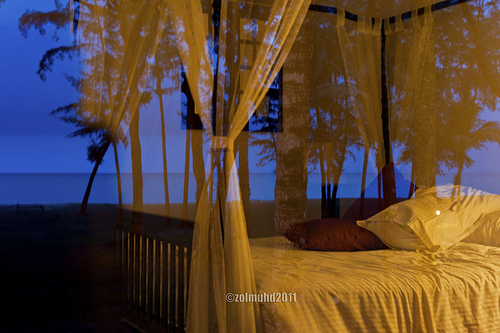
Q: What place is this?
A: It is a beach.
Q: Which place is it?
A: It is a beach.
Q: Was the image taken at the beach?
A: Yes, it was taken in the beach.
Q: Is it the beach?
A: Yes, it is the beach.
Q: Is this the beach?
A: Yes, it is the beach.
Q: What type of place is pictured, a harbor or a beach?
A: It is a beach.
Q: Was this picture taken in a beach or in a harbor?
A: It was taken at a beach.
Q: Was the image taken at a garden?
A: No, the picture was taken in a beach.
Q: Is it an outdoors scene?
A: Yes, it is outdoors.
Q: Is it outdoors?
A: Yes, it is outdoors.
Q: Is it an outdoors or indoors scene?
A: It is outdoors.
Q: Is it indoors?
A: No, it is outdoors.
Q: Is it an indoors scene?
A: No, it is outdoors.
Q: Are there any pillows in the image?
A: Yes, there are pillows.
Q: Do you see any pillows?
A: Yes, there are pillows.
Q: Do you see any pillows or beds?
A: Yes, there are pillows.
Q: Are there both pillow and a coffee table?
A: No, there are pillows but no coffee tables.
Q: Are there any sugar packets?
A: No, there are no sugar packets.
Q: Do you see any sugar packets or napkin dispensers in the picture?
A: No, there are no sugar packets or napkin dispensers.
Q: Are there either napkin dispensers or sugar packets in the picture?
A: No, there are no sugar packets or napkin dispensers.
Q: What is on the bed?
A: The pillows are on the bed.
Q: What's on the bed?
A: The pillows are on the bed.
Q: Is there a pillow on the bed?
A: Yes, there are pillows on the bed.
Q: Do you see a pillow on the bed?
A: Yes, there are pillows on the bed.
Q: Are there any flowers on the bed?
A: No, there are pillows on the bed.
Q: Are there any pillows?
A: Yes, there is a pillow.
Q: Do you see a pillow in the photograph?
A: Yes, there is a pillow.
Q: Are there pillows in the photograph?
A: Yes, there is a pillow.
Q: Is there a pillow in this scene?
A: Yes, there is a pillow.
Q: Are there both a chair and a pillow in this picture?
A: No, there is a pillow but no chairs.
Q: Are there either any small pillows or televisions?
A: Yes, there is a small pillow.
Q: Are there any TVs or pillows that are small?
A: Yes, the pillow is small.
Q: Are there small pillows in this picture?
A: Yes, there is a small pillow.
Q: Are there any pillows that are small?
A: Yes, there is a pillow that is small.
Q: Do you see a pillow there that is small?
A: Yes, there is a pillow that is small.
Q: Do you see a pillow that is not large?
A: Yes, there is a small pillow.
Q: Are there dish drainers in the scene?
A: No, there are no dish drainers.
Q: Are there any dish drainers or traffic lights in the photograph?
A: No, there are no dish drainers or traffic lights.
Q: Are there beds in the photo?
A: Yes, there is a bed.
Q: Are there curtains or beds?
A: Yes, there is a bed.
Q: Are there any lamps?
A: No, there are no lamps.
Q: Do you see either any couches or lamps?
A: No, there are no lamps or couches.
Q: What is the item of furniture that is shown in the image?
A: The piece of furniture is a bed.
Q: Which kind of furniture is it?
A: The piece of furniture is a bed.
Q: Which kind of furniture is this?
A: This is a bed.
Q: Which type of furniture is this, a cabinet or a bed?
A: This is a bed.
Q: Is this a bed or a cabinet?
A: This is a bed.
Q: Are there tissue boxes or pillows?
A: Yes, there is a pillow.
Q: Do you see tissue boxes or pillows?
A: Yes, there is a pillow.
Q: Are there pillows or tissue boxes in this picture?
A: Yes, there is a pillow.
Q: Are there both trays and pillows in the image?
A: No, there is a pillow but no trays.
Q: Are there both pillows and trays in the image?
A: No, there is a pillow but no trays.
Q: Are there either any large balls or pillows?
A: Yes, there is a large pillow.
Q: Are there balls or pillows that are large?
A: Yes, the pillow is large.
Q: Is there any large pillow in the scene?
A: Yes, there is a large pillow.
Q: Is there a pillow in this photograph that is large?
A: Yes, there is a pillow that is large.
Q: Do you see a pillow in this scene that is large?
A: Yes, there is a pillow that is large.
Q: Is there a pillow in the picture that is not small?
A: Yes, there is a large pillow.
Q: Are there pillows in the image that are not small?
A: Yes, there is a large pillow.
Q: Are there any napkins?
A: No, there are no napkins.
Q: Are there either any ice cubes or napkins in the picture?
A: No, there are no napkins or ice cubes.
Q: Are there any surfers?
A: No, there are no surfers.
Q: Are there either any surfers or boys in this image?
A: No, there are no surfers or boys.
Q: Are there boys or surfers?
A: No, there are no surfers or boys.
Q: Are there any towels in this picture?
A: No, there are no towels.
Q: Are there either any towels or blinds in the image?
A: No, there are no towels or blinds.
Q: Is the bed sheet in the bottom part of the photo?
A: Yes, the bed sheet is in the bottom of the image.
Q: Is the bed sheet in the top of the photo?
A: No, the bed sheet is in the bottom of the image.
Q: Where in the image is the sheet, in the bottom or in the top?
A: The sheet is in the bottom of the image.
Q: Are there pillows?
A: Yes, there is a pillow.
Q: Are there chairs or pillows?
A: Yes, there is a pillow.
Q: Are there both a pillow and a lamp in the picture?
A: No, there is a pillow but no lamps.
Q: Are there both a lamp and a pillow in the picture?
A: No, there is a pillow but no lamps.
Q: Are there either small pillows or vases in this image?
A: Yes, there is a small pillow.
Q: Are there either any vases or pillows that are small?
A: Yes, the pillow is small.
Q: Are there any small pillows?
A: Yes, there is a small pillow.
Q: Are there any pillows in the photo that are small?
A: Yes, there is a pillow that is small.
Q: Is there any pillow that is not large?
A: Yes, there is a small pillow.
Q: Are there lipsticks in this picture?
A: No, there are no lipsticks.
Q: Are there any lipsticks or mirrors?
A: No, there are no lipsticks or mirrors.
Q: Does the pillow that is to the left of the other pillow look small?
A: Yes, the pillow is small.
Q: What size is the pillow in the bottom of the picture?
A: The pillow is small.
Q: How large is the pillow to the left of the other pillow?
A: The pillow is small.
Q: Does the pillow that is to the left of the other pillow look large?
A: No, the pillow is small.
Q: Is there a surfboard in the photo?
A: No, there are no surfboards.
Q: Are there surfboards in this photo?
A: No, there are no surfboards.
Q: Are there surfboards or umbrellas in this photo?
A: No, there are no surfboards or umbrellas.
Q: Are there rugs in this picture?
A: No, there are no rugs.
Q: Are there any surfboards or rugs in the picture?
A: No, there are no rugs or surfboards.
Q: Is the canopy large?
A: Yes, the canopy is large.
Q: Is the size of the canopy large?
A: Yes, the canopy is large.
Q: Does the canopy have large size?
A: Yes, the canopy is large.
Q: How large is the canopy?
A: The canopy is large.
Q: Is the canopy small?
A: No, the canopy is large.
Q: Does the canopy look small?
A: No, the canopy is large.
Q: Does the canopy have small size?
A: No, the canopy is large.